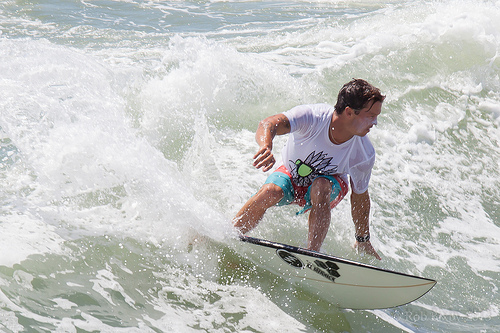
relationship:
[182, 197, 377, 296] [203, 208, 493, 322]
line down center of surfboard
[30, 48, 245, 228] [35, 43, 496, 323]
froth on top of water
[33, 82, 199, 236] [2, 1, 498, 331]
splash in ocean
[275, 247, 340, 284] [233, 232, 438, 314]
design on board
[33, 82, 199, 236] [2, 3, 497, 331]
splash in water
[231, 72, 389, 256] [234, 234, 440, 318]
man wearing shorts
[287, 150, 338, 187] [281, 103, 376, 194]
design on t-shirt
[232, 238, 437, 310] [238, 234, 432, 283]
white surfboard with details